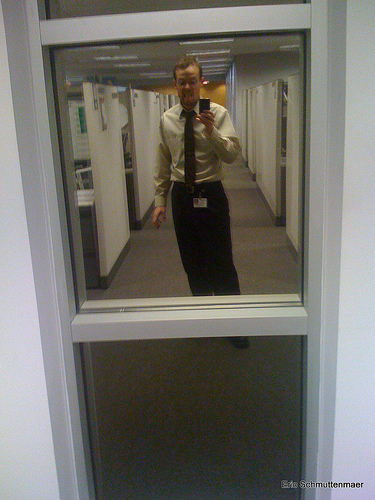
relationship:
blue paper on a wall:
[78, 103, 88, 134] [66, 92, 87, 162]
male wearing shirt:
[153, 57, 251, 348] [155, 102, 240, 207]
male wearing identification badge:
[153, 57, 251, 348] [190, 195, 208, 210]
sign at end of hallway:
[202, 79, 208, 87] [109, 76, 301, 302]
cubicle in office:
[66, 81, 100, 281] [52, 56, 303, 293]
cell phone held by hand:
[198, 98, 210, 113] [192, 109, 219, 126]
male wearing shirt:
[153, 57, 251, 348] [158, 94, 238, 181]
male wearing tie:
[153, 57, 251, 348] [180, 108, 200, 199]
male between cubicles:
[153, 57, 251, 348] [81, 79, 307, 275]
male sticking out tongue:
[153, 57, 251, 348] [177, 85, 203, 106]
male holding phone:
[153, 57, 251, 348] [194, 93, 208, 116]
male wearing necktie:
[153, 57, 251, 348] [176, 107, 202, 191]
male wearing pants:
[153, 57, 251, 348] [164, 178, 241, 299]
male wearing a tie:
[153, 57, 251, 348] [175, 108, 207, 196]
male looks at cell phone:
[153, 57, 251, 348] [198, 98, 210, 113]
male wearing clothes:
[153, 57, 251, 348] [154, 103, 242, 289]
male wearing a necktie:
[153, 57, 251, 348] [179, 109, 197, 185]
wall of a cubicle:
[82, 80, 127, 289] [61, 81, 133, 291]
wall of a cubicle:
[135, 79, 162, 226] [112, 83, 164, 231]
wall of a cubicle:
[285, 70, 300, 252] [156, 91, 191, 178]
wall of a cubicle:
[233, 54, 301, 262] [278, 72, 305, 262]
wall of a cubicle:
[233, 54, 301, 262] [237, 80, 283, 219]